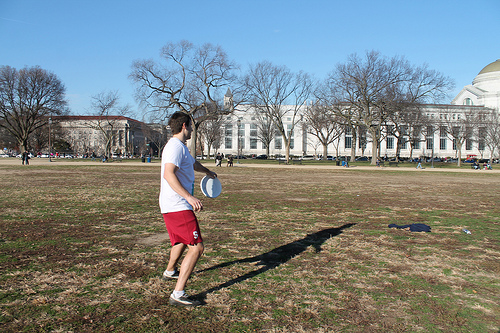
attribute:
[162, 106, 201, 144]
hair — brown, short, dark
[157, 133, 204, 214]
shirt — white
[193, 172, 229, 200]
frisbee — white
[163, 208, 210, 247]
shorts — red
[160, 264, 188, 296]
socks — white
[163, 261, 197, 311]
shoes — dark, black, white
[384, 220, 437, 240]
clothing — blue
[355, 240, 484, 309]
grass — brown, green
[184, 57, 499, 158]
building — large, white, long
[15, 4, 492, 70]
sky — blue, clear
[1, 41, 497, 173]
trees — bare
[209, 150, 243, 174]
people — walking